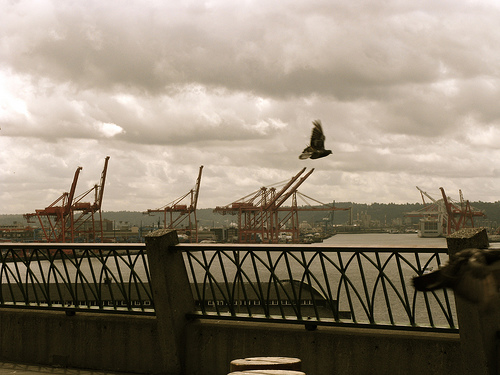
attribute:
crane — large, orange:
[30, 160, 122, 257]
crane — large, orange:
[144, 167, 211, 243]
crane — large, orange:
[213, 165, 350, 243]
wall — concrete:
[0, 232, 479, 342]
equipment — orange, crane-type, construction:
[19, 153, 130, 240]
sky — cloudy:
[0, 0, 498, 204]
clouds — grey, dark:
[1, 0, 499, 203]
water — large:
[314, 226, 454, 296]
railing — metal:
[2, 238, 492, 335]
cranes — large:
[46, 151, 337, 251]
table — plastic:
[227, 354, 304, 373]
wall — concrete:
[0, 305, 499, 373]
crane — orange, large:
[440, 188, 483, 233]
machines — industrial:
[88, 202, 422, 351]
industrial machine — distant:
[411, 185, 485, 239]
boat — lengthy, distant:
[281, 174, 472, 261]